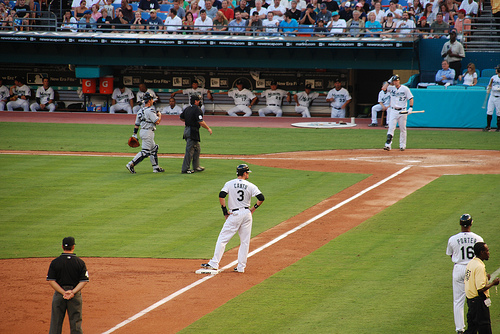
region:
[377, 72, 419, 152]
Baseball player with bat in hand.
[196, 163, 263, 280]
Cano standing on third base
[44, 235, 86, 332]
Umpire with hands behind his back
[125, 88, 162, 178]
Catcher walking to home plate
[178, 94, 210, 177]
Umpire in the infield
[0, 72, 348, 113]
Players sitting in the dugouot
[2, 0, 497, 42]
People sitting in the stands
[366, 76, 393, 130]
Player kneeling outside dugout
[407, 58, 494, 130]
Two people sitting behind blue padded area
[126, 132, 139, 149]
Baseball glove in catcher's left hand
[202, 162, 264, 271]
The baseball player is waiting.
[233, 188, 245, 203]
The number 3 is on the player's shirt.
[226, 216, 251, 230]
The pants are white.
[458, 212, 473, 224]
The player wears a helmet.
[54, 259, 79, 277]
The shirt is black.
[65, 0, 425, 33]
People watch the game from the stands.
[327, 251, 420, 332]
The field is green.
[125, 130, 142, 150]
The player holds a glove.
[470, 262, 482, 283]
The shirt is yellow.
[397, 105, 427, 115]
The player holds a bat.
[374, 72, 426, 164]
A baseball player in white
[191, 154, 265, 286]
A baseball player in white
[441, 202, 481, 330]
A baseball player in white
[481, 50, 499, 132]
A baseball player in white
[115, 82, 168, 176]
A baseball player in white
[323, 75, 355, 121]
A baseball player in white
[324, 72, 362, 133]
A baseball player in white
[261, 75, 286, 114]
A baseball player in white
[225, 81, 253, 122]
A baseball player in white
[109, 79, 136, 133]
A baseball player in white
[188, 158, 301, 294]
this is a man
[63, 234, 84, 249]
this is a cap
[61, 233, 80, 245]
the cap is black in color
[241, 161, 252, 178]
the helmet is black in color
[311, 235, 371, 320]
this is a grass area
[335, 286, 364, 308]
the grass is green in color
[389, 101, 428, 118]
this is a bat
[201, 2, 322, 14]
these are the fans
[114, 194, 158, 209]
this is the grass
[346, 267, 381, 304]
the grass is green in color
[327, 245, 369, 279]
the grass is short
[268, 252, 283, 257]
this is the ground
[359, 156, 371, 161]
the ground is sandy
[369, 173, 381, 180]
the sand is brown in color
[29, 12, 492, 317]
these are some people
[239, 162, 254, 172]
the helmet is black in color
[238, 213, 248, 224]
the trouser is white in color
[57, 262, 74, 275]
the t shirt is black in color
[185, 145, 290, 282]
Man wearing black helmet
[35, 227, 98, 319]
Man wearing black cap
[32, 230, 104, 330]
Man wearing black shirt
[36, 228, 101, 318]
Man wearing black pants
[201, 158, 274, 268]
Man wearing white pants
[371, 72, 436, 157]
Man holding baseball bat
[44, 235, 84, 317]
A person is standing up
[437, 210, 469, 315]
A person is standing up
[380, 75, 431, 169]
A person is standing up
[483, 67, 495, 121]
A person is standing up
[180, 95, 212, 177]
A person is standing up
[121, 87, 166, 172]
A person is standing up